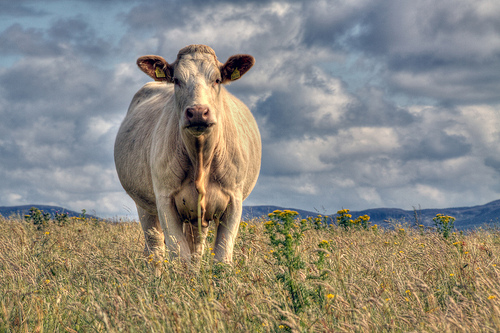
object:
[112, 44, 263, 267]
cow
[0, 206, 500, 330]
field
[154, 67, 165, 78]
tag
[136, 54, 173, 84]
ear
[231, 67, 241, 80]
tag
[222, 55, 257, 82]
ear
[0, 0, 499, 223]
sky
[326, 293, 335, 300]
flowers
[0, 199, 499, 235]
hill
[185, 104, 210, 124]
nose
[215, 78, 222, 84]
eyes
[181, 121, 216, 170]
neck